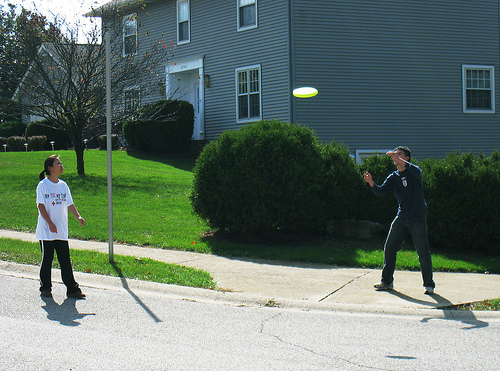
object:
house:
[116, 2, 499, 144]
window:
[173, 1, 194, 44]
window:
[230, 2, 257, 32]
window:
[118, 85, 141, 122]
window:
[230, 63, 266, 124]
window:
[459, 61, 499, 119]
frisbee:
[289, 83, 320, 100]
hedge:
[121, 97, 195, 160]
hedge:
[187, 118, 327, 246]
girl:
[32, 151, 89, 304]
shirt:
[34, 175, 76, 245]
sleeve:
[65, 184, 77, 211]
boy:
[360, 142, 439, 298]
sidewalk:
[146, 271, 500, 303]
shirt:
[364, 161, 433, 221]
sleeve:
[367, 170, 394, 197]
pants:
[379, 209, 435, 296]